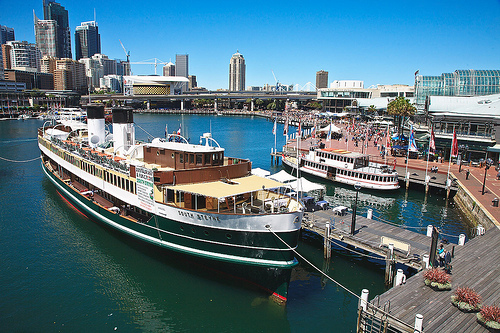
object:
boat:
[35, 104, 306, 270]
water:
[2, 111, 475, 332]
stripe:
[271, 292, 290, 305]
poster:
[134, 165, 158, 214]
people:
[440, 248, 452, 274]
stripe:
[139, 218, 299, 253]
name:
[176, 208, 222, 222]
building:
[413, 69, 500, 110]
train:
[183, 88, 316, 98]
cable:
[266, 225, 359, 299]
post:
[358, 287, 369, 312]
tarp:
[266, 169, 299, 185]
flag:
[449, 125, 462, 157]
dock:
[300, 205, 500, 332]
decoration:
[46, 135, 126, 170]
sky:
[2, 0, 499, 91]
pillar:
[109, 106, 136, 155]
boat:
[281, 146, 401, 193]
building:
[0, 89, 66, 116]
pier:
[354, 287, 373, 333]